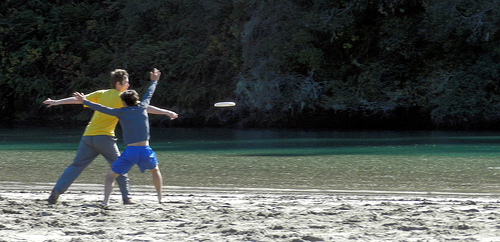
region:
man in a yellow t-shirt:
[41, 69, 175, 204]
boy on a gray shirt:
[75, 67, 162, 214]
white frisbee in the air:
[211, 99, 239, 111]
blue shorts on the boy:
[108, 144, 158, 177]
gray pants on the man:
[49, 134, 129, 204]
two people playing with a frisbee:
[38, 67, 178, 204]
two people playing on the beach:
[38, 66, 176, 207]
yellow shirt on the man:
[78, 89, 138, 136]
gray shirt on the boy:
[79, 78, 159, 147]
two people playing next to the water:
[43, 67, 179, 208]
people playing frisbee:
[51, 70, 235, 192]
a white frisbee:
[212, 100, 233, 106]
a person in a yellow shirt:
[63, 78, 130, 149]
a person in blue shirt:
[106, 85, 161, 159]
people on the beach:
[53, 62, 168, 197]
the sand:
[71, 199, 488, 235]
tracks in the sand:
[23, 205, 486, 238]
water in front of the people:
[193, 126, 493, 182]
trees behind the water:
[6, 6, 480, 112]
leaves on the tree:
[414, 75, 496, 104]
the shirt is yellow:
[75, 82, 124, 139]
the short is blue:
[109, 146, 166, 183]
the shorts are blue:
[137, 149, 152, 163]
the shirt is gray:
[126, 114, 138, 132]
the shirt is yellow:
[95, 115, 108, 130]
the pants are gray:
[74, 156, 84, 168]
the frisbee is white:
[213, 99, 236, 111]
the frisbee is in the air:
[211, 99, 238, 111]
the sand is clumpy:
[266, 206, 298, 235]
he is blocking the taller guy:
[112, 65, 159, 151]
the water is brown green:
[386, 163, 418, 184]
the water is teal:
[318, 144, 348, 154]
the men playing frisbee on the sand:
[25, 49, 244, 209]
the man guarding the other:
[76, 63, 166, 210]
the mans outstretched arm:
[144, 101, 179, 121]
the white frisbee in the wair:
[210, 93, 236, 112]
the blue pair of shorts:
[113, 141, 160, 171]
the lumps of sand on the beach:
[33, 203, 499, 240]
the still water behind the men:
[245, 119, 497, 187]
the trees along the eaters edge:
[235, 0, 497, 115]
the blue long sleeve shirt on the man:
[85, 85, 165, 147]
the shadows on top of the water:
[199, 126, 482, 158]